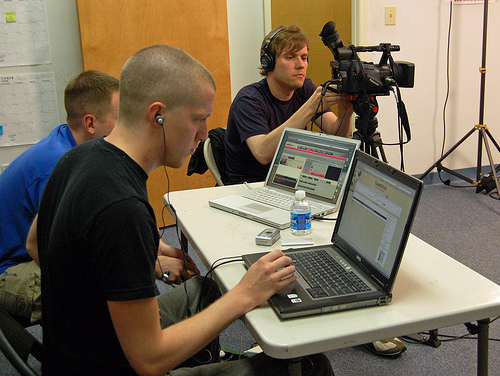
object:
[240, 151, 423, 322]
laptop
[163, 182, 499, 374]
table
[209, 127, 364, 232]
laptop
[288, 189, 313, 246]
bottle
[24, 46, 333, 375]
guy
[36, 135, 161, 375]
tshirt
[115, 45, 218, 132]
hair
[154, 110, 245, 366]
earphones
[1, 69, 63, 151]
calendar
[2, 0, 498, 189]
wall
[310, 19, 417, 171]
recording equipment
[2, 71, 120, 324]
man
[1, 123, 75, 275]
tshirt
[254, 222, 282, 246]
cell phone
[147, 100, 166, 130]
ear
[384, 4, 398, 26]
light switch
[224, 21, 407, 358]
person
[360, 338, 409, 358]
sneaker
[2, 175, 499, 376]
floor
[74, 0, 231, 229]
door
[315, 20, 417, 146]
camera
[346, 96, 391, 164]
tripod